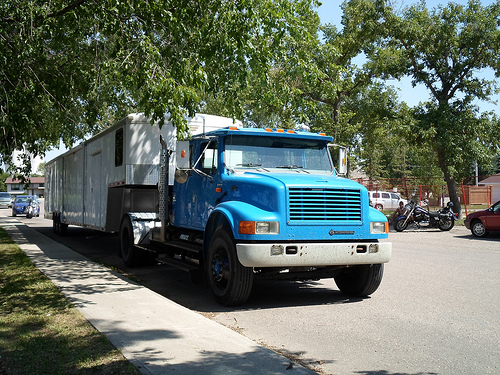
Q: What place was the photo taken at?
A: It was taken at the street.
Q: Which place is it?
A: It is a street.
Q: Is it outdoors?
A: Yes, it is outdoors.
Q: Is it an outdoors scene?
A: Yes, it is outdoors.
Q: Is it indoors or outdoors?
A: It is outdoors.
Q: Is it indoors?
A: No, it is outdoors.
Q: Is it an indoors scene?
A: No, it is outdoors.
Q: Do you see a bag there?
A: No, there are no bags.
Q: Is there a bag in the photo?
A: No, there are no bags.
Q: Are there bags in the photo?
A: No, there are no bags.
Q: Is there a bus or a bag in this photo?
A: No, there are no bags or buses.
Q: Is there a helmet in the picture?
A: No, there are no helmets.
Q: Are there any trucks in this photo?
A: Yes, there is a truck.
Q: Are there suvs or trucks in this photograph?
A: Yes, there is a truck.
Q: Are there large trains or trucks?
A: Yes, there is a large truck.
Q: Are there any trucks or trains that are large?
A: Yes, the truck is large.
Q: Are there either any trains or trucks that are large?
A: Yes, the truck is large.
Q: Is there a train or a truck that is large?
A: Yes, the truck is large.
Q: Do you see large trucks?
A: Yes, there is a large truck.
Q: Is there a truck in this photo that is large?
A: Yes, there is a truck that is large.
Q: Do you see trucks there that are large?
A: Yes, there is a truck that is large.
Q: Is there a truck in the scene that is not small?
A: Yes, there is a large truck.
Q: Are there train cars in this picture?
A: No, there are no train cars.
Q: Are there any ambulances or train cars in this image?
A: No, there are no train cars or ambulances.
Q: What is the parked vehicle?
A: The vehicle is a truck.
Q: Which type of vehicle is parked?
A: The vehicle is a truck.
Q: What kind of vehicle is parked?
A: The vehicle is a truck.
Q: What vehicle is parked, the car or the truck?
A: The truck is parked.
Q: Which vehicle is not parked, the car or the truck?
A: The car is not parked.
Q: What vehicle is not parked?
A: The vehicle is a car.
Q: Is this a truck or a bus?
A: This is a truck.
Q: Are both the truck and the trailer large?
A: Yes, both the truck and the trailer are large.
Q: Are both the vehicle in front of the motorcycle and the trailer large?
A: Yes, both the truck and the trailer are large.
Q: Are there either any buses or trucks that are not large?
A: No, there is a truck but it is large.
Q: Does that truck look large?
A: Yes, the truck is large.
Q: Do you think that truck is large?
A: Yes, the truck is large.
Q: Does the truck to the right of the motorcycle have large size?
A: Yes, the truck is large.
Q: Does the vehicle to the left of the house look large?
A: Yes, the truck is large.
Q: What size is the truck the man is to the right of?
A: The truck is large.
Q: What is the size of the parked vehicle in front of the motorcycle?
A: The truck is large.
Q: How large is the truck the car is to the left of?
A: The truck is large.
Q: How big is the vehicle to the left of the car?
A: The truck is large.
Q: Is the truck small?
A: No, the truck is large.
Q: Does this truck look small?
A: No, the truck is large.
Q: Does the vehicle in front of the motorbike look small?
A: No, the truck is large.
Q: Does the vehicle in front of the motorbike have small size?
A: No, the truck is large.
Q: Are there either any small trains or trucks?
A: No, there is a truck but it is large.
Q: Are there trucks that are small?
A: No, there is a truck but it is large.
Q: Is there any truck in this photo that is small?
A: No, there is a truck but it is large.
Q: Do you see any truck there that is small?
A: No, there is a truck but it is large.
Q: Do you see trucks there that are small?
A: No, there is a truck but it is large.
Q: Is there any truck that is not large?
A: No, there is a truck but it is large.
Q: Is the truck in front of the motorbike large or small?
A: The truck is large.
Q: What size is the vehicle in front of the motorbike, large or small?
A: The truck is large.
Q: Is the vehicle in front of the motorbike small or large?
A: The truck is large.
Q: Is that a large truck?
A: Yes, that is a large truck.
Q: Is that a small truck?
A: No, that is a large truck.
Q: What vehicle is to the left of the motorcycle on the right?
A: The vehicle is a truck.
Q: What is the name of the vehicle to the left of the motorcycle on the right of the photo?
A: The vehicle is a truck.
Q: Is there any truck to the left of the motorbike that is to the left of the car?
A: Yes, there is a truck to the left of the motorcycle.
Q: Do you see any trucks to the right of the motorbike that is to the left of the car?
A: No, the truck is to the left of the motorcycle.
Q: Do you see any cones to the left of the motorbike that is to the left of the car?
A: No, there is a truck to the left of the motorbike.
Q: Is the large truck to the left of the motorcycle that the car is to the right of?
A: Yes, the truck is to the left of the motorcycle.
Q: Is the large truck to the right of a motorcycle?
A: No, the truck is to the left of a motorcycle.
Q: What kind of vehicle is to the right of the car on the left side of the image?
A: The vehicle is a truck.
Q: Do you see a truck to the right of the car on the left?
A: Yes, there is a truck to the right of the car.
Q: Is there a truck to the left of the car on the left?
A: No, the truck is to the right of the car.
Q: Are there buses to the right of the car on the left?
A: No, there is a truck to the right of the car.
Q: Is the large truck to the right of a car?
A: Yes, the truck is to the right of a car.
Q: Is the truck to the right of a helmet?
A: No, the truck is to the right of a car.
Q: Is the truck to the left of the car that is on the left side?
A: No, the truck is to the right of the car.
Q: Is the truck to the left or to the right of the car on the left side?
A: The truck is to the right of the car.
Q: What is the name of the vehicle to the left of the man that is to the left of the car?
A: The vehicle is a truck.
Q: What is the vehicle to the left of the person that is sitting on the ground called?
A: The vehicle is a truck.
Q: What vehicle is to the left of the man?
A: The vehicle is a truck.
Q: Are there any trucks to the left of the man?
A: Yes, there is a truck to the left of the man.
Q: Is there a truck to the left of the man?
A: Yes, there is a truck to the left of the man.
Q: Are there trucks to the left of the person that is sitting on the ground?
A: Yes, there is a truck to the left of the man.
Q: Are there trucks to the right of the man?
A: No, the truck is to the left of the man.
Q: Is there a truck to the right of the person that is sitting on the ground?
A: No, the truck is to the left of the man.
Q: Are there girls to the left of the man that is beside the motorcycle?
A: No, there is a truck to the left of the man.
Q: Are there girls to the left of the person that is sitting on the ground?
A: No, there is a truck to the left of the man.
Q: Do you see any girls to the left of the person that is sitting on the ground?
A: No, there is a truck to the left of the man.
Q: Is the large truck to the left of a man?
A: Yes, the truck is to the left of a man.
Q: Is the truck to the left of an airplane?
A: No, the truck is to the left of a man.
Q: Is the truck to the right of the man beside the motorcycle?
A: No, the truck is to the left of the man.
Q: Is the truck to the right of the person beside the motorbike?
A: No, the truck is to the left of the man.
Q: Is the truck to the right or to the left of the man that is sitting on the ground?
A: The truck is to the left of the man.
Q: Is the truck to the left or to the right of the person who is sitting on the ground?
A: The truck is to the left of the man.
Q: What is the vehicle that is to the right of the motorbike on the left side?
A: The vehicle is a truck.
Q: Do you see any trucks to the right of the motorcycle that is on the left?
A: Yes, there is a truck to the right of the motorbike.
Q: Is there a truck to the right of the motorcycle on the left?
A: Yes, there is a truck to the right of the motorbike.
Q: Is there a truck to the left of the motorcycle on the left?
A: No, the truck is to the right of the motorcycle.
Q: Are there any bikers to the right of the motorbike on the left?
A: No, there is a truck to the right of the motorbike.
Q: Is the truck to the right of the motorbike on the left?
A: Yes, the truck is to the right of the motorcycle.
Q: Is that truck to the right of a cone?
A: No, the truck is to the right of the motorcycle.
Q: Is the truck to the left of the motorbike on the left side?
A: No, the truck is to the right of the motorbike.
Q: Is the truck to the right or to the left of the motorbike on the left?
A: The truck is to the right of the motorbike.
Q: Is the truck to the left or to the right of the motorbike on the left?
A: The truck is to the right of the motorbike.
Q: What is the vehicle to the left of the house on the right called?
A: The vehicle is a truck.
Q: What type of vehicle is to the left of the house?
A: The vehicle is a truck.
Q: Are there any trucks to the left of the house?
A: Yes, there is a truck to the left of the house.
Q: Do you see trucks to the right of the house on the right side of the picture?
A: No, the truck is to the left of the house.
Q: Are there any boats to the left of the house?
A: No, there is a truck to the left of the house.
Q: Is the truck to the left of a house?
A: Yes, the truck is to the left of a house.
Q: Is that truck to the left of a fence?
A: No, the truck is to the left of a house.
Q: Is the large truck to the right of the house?
A: No, the truck is to the left of the house.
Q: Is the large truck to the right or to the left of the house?
A: The truck is to the left of the house.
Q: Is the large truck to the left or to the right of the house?
A: The truck is to the left of the house.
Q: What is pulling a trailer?
A: The truck is pulling a trailer.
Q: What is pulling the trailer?
A: The truck is pulling a trailer.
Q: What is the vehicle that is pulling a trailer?
A: The vehicle is a truck.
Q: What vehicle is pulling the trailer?
A: The vehicle is a truck.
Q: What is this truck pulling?
A: The truck is pulling a trailer.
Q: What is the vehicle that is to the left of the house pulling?
A: The truck is pulling a trailer.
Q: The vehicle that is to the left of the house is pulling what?
A: The truck is pulling a trailer.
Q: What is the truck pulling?
A: The truck is pulling a trailer.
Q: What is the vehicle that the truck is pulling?
A: The vehicle is a trailer.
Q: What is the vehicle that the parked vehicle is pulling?
A: The vehicle is a trailer.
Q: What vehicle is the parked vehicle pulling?
A: The truck is pulling a trailer.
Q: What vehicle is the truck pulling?
A: The truck is pulling a trailer.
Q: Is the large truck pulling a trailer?
A: Yes, the truck is pulling a trailer.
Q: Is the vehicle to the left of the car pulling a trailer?
A: Yes, the truck is pulling a trailer.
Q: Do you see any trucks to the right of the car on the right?
A: No, the truck is to the left of the car.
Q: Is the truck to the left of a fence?
A: No, the truck is to the left of the car.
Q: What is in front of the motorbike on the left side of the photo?
A: The truck is in front of the motorcycle.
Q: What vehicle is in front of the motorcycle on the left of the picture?
A: The vehicle is a truck.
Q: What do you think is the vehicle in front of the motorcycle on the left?
A: The vehicle is a truck.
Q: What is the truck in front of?
A: The truck is in front of the motorbike.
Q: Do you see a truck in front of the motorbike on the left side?
A: Yes, there is a truck in front of the motorbike.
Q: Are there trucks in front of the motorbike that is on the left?
A: Yes, there is a truck in front of the motorbike.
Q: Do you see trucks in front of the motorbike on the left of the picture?
A: Yes, there is a truck in front of the motorbike.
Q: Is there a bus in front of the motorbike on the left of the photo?
A: No, there is a truck in front of the motorbike.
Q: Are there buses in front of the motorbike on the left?
A: No, there is a truck in front of the motorbike.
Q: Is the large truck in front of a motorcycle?
A: Yes, the truck is in front of a motorcycle.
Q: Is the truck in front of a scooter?
A: No, the truck is in front of a motorcycle.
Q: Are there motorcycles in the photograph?
A: Yes, there is a motorcycle.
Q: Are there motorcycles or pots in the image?
A: Yes, there is a motorcycle.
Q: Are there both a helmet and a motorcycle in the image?
A: No, there is a motorcycle but no helmets.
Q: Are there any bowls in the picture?
A: No, there are no bowls.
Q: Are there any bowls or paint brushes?
A: No, there are no bowls or paint brushes.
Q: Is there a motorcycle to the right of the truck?
A: Yes, there is a motorcycle to the right of the truck.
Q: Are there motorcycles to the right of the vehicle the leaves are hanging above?
A: Yes, there is a motorcycle to the right of the truck.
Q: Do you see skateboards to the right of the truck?
A: No, there is a motorcycle to the right of the truck.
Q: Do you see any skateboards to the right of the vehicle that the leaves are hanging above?
A: No, there is a motorcycle to the right of the truck.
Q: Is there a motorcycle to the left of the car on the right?
A: Yes, there is a motorcycle to the left of the car.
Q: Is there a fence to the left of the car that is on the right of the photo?
A: No, there is a motorcycle to the left of the car.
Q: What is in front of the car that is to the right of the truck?
A: The motorcycle is in front of the car.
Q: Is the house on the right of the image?
A: Yes, the house is on the right of the image.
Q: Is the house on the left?
A: No, the house is on the right of the image.